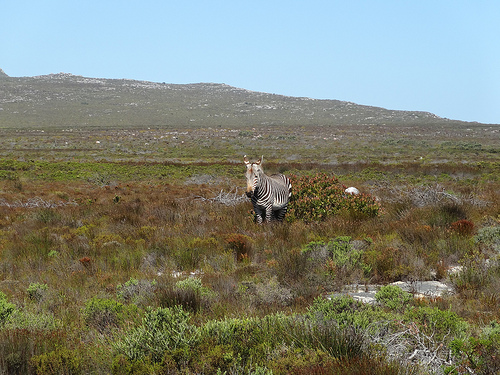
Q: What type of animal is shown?
A: Zebra.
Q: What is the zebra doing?
A: Standing.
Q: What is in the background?
A: Hill.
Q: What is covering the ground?
A: Weeds, shrubs, and other vegetation.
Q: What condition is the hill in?
A: Bare.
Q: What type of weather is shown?
A: Clear.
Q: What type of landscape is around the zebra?
A: Flat.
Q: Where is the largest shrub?
A: Behind the zebra.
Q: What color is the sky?
A: Blue.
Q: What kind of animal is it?
A: A zebra.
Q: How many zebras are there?
A: One.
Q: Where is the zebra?
A: In the wilderness.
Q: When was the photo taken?
A: Daytime.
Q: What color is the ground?
A: Green.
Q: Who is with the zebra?
A: No one.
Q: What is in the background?
A: Mountains.